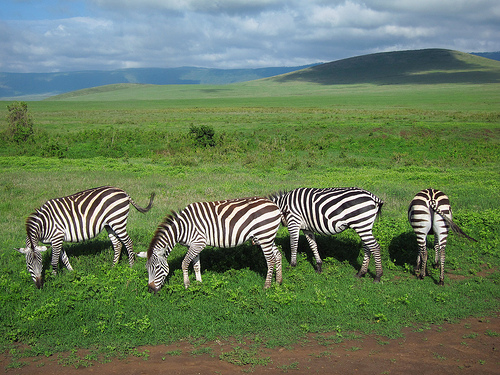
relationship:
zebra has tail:
[13, 180, 161, 292] [129, 187, 164, 217]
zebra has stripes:
[13, 180, 161, 292] [52, 200, 102, 231]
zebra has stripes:
[143, 195, 287, 295] [198, 205, 255, 238]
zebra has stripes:
[252, 181, 389, 284] [294, 196, 355, 224]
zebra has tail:
[407, 186, 456, 286] [428, 198, 488, 248]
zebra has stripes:
[407, 186, 456, 286] [411, 191, 449, 225]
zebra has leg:
[252, 181, 389, 284] [302, 232, 326, 275]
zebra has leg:
[252, 181, 389, 284] [285, 223, 304, 271]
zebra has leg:
[252, 181, 389, 284] [358, 231, 386, 286]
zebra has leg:
[407, 186, 456, 286] [409, 214, 431, 282]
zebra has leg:
[407, 186, 456, 286] [435, 227, 453, 288]